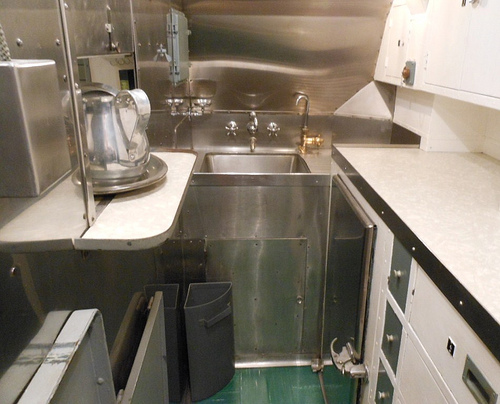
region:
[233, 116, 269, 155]
faucet in the sink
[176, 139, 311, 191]
sink in the photo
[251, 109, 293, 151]
silver knob in photo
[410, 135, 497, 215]
counter top in the photo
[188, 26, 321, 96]
light hitting the wall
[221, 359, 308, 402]
green ground in photo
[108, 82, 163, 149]
handle of the object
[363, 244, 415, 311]
knob on the droor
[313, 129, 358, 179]
edge of the counter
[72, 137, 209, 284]
tabel top in photo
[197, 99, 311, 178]
stainless steel industrial sink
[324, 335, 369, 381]
handle of refrigeration unit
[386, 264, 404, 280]
stainless steel drawer pull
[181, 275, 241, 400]
corner bin for trash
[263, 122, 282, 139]
faucet for stainless steel sink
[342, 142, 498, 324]
counter with nothing on it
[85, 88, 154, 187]
large stainless steel picher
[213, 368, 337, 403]
dark green linoleum floor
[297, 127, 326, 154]
gold colored side faucet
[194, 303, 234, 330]
handle for corner bin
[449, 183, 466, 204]
part of a table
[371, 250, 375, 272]
edge of a table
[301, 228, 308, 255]
part of a sink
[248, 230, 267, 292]
edge of a sink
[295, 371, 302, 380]
part of a floor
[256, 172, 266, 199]
edge of a sink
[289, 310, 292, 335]
edge of a floor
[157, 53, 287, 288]
A nasty kitchen area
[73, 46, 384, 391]
A nasty kitchen area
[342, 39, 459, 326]
A nasty kitchen area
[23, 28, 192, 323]
A nasty kitchen area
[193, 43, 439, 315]
A nasty kitchen area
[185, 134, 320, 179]
the sink is silver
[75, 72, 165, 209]
the kettle is silver